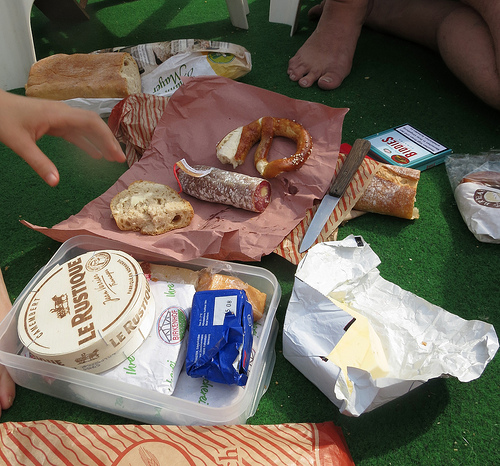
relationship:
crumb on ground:
[352, 70, 378, 90] [40, 5, 487, 377]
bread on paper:
[216, 115, 314, 179] [283, 228, 496, 418]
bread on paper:
[216, 115, 314, 179] [19, 36, 380, 260]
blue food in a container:
[186, 288, 254, 387] [1, 220, 290, 436]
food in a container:
[108, 115, 314, 236] [1, 220, 290, 436]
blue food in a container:
[186, 278, 252, 388] [0, 351, 270, 428]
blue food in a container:
[186, 288, 254, 387] [1, 234, 282, 425]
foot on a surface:
[285, 5, 371, 90] [0, 0, 498, 465]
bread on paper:
[216, 115, 314, 179] [20, 65, 352, 281]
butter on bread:
[128, 193, 156, 203] [109, 179, 195, 235]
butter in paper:
[325, 293, 380, 390] [283, 228, 496, 418]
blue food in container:
[186, 288, 254, 387] [18, 231, 289, 373]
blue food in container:
[186, 288, 254, 387] [54, 220, 269, 371]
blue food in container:
[186, 288, 254, 387] [12, 221, 242, 380]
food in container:
[78, 75, 361, 252] [32, 185, 316, 449]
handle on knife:
[312, 145, 371, 195] [307, 141, 373, 239]